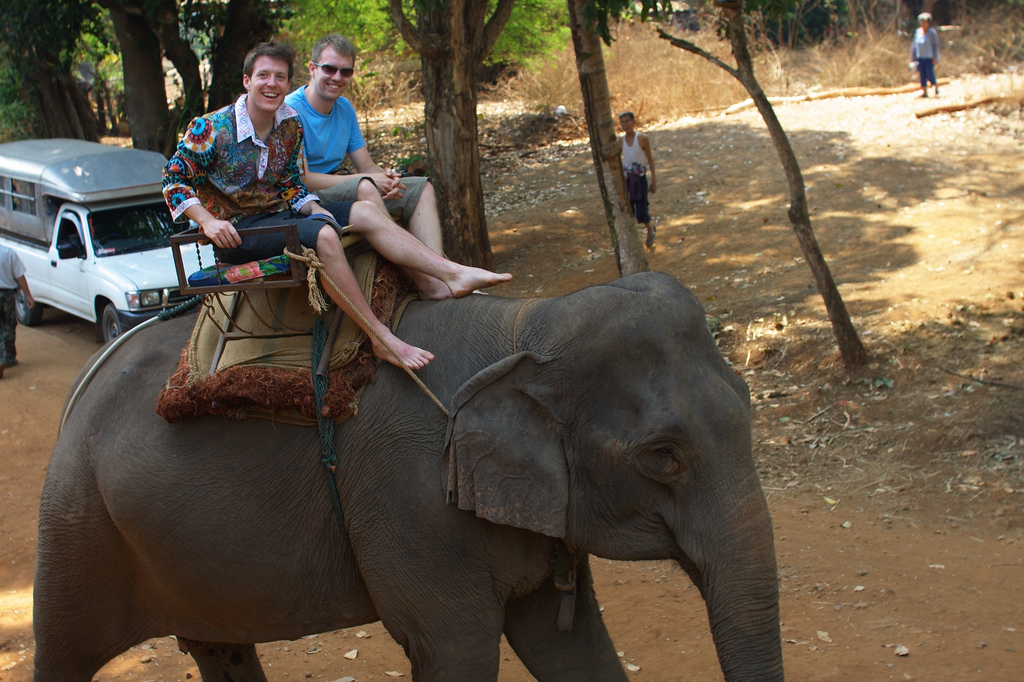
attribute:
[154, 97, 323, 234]
shirt — colorful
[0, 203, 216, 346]
truck — white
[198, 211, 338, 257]
shorts — blue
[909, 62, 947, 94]
pants — blue, capri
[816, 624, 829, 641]
leaf — dead 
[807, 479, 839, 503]
leaf — dead 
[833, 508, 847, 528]
leaf — dead 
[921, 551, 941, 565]
leaf — dead 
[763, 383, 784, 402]
leaf — dead 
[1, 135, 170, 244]
camper shell — silver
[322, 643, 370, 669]
leaf — dead 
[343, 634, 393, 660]
leaf — dead 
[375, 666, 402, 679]
leaf — dead 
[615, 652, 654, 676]
leaf — dead 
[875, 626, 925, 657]
leaf — dead 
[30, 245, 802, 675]
elephant — gray